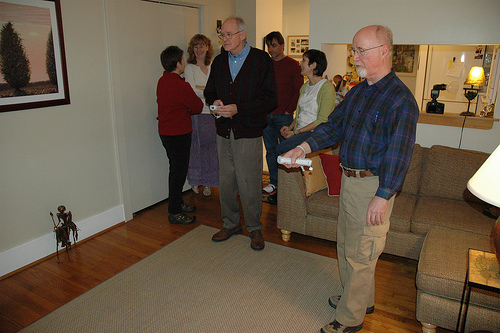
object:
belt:
[339, 163, 374, 178]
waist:
[340, 152, 397, 178]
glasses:
[217, 29, 245, 40]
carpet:
[18, 224, 342, 333]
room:
[0, 0, 500, 333]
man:
[263, 31, 304, 194]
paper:
[446, 61, 465, 78]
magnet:
[452, 56, 456, 62]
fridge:
[421, 45, 487, 115]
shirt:
[228, 41, 252, 82]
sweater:
[203, 45, 279, 140]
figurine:
[49, 204, 81, 263]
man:
[277, 24, 419, 333]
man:
[203, 16, 279, 250]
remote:
[210, 105, 222, 119]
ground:
[419, 119, 491, 144]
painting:
[0, 0, 71, 113]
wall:
[0, 2, 110, 279]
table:
[466, 248, 499, 290]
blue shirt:
[304, 68, 421, 201]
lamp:
[459, 65, 486, 115]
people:
[155, 45, 203, 224]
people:
[184, 33, 220, 196]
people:
[276, 49, 336, 162]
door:
[105, 0, 207, 215]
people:
[202, 16, 280, 250]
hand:
[282, 145, 311, 169]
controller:
[277, 156, 314, 171]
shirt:
[156, 71, 204, 136]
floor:
[0, 172, 416, 333]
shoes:
[319, 318, 365, 333]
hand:
[215, 104, 238, 117]